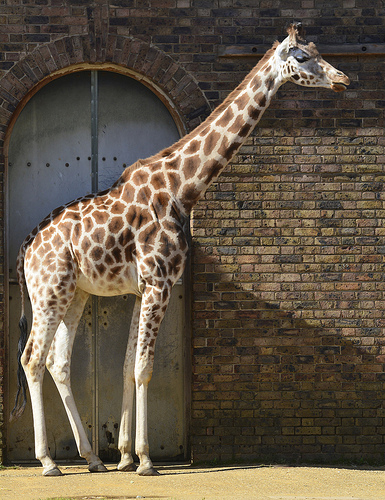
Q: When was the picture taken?
A: During the day.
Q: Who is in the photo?
A: Nobody.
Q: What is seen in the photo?
A: A giraffe.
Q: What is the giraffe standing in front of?
A: A door.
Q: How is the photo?
A: Clear.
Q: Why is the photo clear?
A: It is daytime.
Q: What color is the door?
A: Grey.